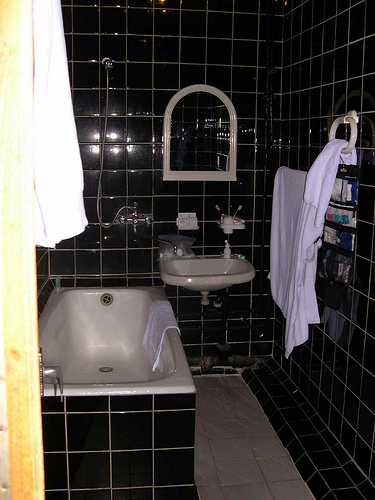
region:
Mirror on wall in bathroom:
[163, 83, 236, 180]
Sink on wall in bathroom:
[152, 235, 253, 305]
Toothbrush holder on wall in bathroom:
[212, 202, 241, 232]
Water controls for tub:
[114, 201, 150, 232]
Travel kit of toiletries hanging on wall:
[321, 165, 353, 307]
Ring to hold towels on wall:
[326, 109, 359, 154]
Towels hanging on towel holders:
[267, 138, 356, 358]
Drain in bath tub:
[98, 364, 113, 373]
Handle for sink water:
[153, 236, 179, 255]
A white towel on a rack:
[268, 167, 315, 348]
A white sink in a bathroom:
[158, 253, 253, 299]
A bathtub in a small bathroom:
[40, 280, 200, 498]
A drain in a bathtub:
[100, 364, 112, 374]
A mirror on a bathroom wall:
[160, 85, 243, 184]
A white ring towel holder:
[328, 109, 359, 152]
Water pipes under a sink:
[203, 290, 234, 357]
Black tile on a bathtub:
[44, 397, 191, 499]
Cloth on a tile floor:
[190, 370, 307, 495]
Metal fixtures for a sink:
[94, 55, 154, 233]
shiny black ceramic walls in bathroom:
[47, 3, 373, 494]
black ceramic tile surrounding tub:
[47, 401, 196, 494]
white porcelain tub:
[48, 276, 192, 400]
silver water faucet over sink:
[154, 235, 180, 255]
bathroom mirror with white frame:
[161, 81, 238, 184]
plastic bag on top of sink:
[156, 232, 196, 260]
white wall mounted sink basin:
[156, 253, 256, 293]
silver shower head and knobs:
[95, 54, 154, 234]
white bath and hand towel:
[267, 137, 358, 357]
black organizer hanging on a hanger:
[313, 149, 359, 313]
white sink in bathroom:
[156, 251, 258, 308]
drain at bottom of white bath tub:
[95, 362, 115, 375]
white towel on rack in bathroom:
[263, 163, 322, 366]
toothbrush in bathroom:
[227, 201, 245, 220]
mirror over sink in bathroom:
[156, 81, 241, 185]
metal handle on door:
[36, 346, 67, 408]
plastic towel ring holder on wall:
[323, 107, 362, 155]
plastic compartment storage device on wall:
[308, 166, 363, 312]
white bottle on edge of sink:
[221, 236, 232, 258]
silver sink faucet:
[146, 232, 180, 258]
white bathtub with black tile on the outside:
[42, 284, 194, 496]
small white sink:
[156, 253, 255, 304]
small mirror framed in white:
[162, 84, 238, 182]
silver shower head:
[102, 55, 114, 68]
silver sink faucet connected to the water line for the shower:
[130, 216, 177, 254]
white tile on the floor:
[187, 372, 312, 495]